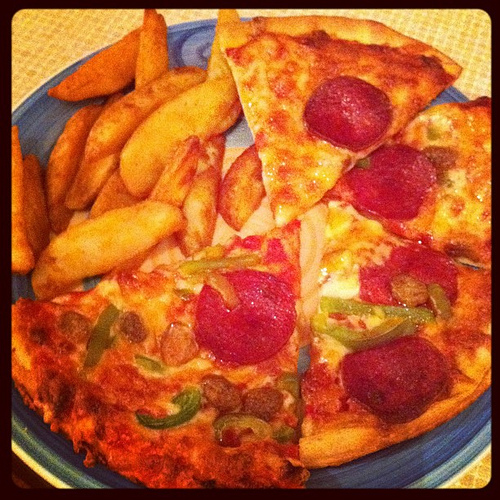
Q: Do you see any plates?
A: Yes, there is a plate.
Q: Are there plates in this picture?
A: Yes, there is a plate.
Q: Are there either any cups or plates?
A: Yes, there is a plate.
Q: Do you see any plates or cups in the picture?
A: Yes, there is a plate.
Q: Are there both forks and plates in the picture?
A: No, there is a plate but no forks.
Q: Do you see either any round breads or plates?
A: Yes, there is a round plate.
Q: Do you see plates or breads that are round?
A: Yes, the plate is round.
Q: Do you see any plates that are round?
A: Yes, there is a round plate.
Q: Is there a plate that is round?
A: Yes, there is a plate that is round.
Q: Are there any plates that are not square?
A: Yes, there is a round plate.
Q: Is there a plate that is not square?
A: Yes, there is a round plate.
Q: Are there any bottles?
A: No, there are no bottles.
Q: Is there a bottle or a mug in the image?
A: No, there are no bottles or mugs.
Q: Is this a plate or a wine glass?
A: This is a plate.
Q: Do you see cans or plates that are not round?
A: No, there is a plate but it is round.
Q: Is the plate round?
A: Yes, the plate is round.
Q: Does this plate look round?
A: Yes, the plate is round.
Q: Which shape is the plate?
A: The plate is round.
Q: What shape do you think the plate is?
A: The plate is round.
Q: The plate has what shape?
A: The plate is round.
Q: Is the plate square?
A: No, the plate is round.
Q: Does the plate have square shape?
A: No, the plate is round.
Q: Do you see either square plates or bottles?
A: No, there is a plate but it is round.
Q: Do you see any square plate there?
A: No, there is a plate but it is round.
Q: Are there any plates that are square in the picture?
A: No, there is a plate but it is round.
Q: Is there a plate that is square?
A: No, there is a plate but it is round.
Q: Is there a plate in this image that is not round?
A: No, there is a plate but it is round.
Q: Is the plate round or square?
A: The plate is round.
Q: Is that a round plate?
A: Yes, that is a round plate.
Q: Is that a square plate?
A: No, that is a round plate.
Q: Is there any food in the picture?
A: Yes, there is food.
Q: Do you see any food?
A: Yes, there is food.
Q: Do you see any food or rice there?
A: Yes, there is food.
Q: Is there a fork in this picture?
A: No, there are no forks.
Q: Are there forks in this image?
A: No, there are no forks.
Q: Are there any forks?
A: No, there are no forks.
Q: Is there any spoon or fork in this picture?
A: No, there are no forks or spoons.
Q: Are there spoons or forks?
A: No, there are no forks or spoons.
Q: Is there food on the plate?
A: Yes, there is food on the plate.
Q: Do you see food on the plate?
A: Yes, there is food on the plate.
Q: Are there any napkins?
A: No, there are no napkins.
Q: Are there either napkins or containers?
A: No, there are no napkins or containers.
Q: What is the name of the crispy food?
A: The food is fries.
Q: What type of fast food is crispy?
A: The fast food is fries.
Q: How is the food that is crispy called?
A: The food is fries.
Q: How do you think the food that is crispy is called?
A: The food is fries.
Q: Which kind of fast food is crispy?
A: The fast food is fries.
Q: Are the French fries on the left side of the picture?
A: Yes, the French fries are on the left of the image.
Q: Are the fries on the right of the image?
A: No, the fries are on the left of the image.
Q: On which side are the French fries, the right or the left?
A: The French fries are on the left of the image.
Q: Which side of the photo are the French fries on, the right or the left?
A: The French fries are on the left of the image.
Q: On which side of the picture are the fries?
A: The fries are on the left of the image.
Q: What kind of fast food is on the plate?
A: The food is fries.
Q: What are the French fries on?
A: The French fries are on the plate.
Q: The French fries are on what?
A: The French fries are on the plate.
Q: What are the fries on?
A: The French fries are on the plate.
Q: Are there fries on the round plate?
A: Yes, there are fries on the plate.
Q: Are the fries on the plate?
A: Yes, the fries are on the plate.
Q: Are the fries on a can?
A: No, the fries are on the plate.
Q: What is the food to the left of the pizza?
A: The food is fries.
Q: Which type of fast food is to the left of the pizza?
A: The food is fries.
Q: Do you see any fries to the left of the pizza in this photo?
A: Yes, there are fries to the left of the pizza.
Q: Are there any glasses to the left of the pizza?
A: No, there are fries to the left of the pizza.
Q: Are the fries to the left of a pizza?
A: Yes, the fries are to the left of a pizza.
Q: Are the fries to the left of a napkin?
A: No, the fries are to the left of a pizza.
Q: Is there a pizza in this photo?
A: Yes, there is a pizza.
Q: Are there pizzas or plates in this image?
A: Yes, there is a pizza.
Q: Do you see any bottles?
A: No, there are no bottles.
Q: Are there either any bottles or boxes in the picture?
A: No, there are no bottles or boxes.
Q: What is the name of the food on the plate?
A: The food is a pizza.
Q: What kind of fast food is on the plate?
A: The food is a pizza.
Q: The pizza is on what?
A: The pizza is on the plate.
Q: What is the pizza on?
A: The pizza is on the plate.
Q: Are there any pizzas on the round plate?
A: Yes, there is a pizza on the plate.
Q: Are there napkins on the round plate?
A: No, there is a pizza on the plate.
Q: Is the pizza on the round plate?
A: Yes, the pizza is on the plate.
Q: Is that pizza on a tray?
A: No, the pizza is on the plate.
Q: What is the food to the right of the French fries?
A: The food is a pizza.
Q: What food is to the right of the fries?
A: The food is a pizza.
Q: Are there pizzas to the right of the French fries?
A: Yes, there is a pizza to the right of the French fries.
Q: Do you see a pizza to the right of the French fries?
A: Yes, there is a pizza to the right of the French fries.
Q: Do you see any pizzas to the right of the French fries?
A: Yes, there is a pizza to the right of the French fries.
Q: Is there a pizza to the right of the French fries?
A: Yes, there is a pizza to the right of the French fries.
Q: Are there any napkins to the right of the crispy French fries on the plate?
A: No, there is a pizza to the right of the fries.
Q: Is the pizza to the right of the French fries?
A: Yes, the pizza is to the right of the French fries.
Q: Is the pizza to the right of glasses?
A: No, the pizza is to the right of the French fries.